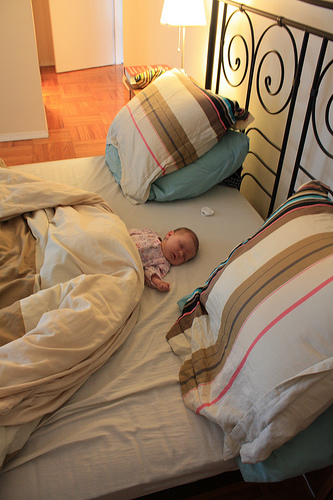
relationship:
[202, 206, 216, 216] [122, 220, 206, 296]
teether for baby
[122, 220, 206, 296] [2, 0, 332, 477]
baby laying in bed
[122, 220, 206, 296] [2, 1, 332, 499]
baby in bedroom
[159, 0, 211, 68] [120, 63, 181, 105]
lamp on table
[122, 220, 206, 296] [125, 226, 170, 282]
baby wearing a onesie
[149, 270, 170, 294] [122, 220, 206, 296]
arm on baby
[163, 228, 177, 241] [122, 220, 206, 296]
ear on baby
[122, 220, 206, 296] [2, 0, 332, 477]
baby laying on bed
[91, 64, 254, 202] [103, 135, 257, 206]
pillow on top of another pillow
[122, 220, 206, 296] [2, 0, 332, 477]
baby in bed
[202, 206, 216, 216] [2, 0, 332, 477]
teether on bed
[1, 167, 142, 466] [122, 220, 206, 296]
comforter covering baby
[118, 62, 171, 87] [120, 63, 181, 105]
book on table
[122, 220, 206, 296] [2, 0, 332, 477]
baby on bed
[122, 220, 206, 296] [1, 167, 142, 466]
baby covered by comforter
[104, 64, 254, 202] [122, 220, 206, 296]
pillow by baby